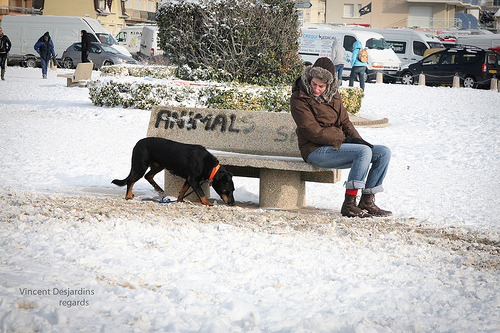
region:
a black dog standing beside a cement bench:
[110, 135, 236, 206]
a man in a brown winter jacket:
[290, 56, 392, 218]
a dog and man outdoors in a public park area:
[110, 56, 392, 216]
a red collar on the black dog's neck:
[209, 161, 219, 181]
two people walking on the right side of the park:
[330, 37, 368, 89]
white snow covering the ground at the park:
[121, 230, 498, 331]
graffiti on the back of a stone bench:
[152, 109, 293, 137]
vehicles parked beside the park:
[0, 13, 499, 85]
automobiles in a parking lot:
[1, 11, 497, 89]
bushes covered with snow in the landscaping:
[87, 63, 287, 106]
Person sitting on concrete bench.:
[81, 37, 413, 247]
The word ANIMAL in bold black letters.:
[138, 97, 264, 135]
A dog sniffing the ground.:
[113, 117, 252, 224]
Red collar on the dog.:
[148, 127, 243, 204]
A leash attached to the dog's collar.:
[148, 133, 236, 216]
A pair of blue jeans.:
[302, 134, 402, 199]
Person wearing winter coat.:
[288, 59, 410, 182]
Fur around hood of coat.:
[279, 46, 350, 121]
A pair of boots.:
[327, 173, 399, 225]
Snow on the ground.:
[11, 82, 485, 317]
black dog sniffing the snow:
[100, 133, 240, 216]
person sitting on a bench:
[287, 48, 404, 225]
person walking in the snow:
[29, 26, 58, 86]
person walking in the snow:
[0, 25, 14, 83]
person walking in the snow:
[75, 25, 96, 69]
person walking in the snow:
[345, 34, 372, 101]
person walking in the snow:
[326, 33, 349, 86]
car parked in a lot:
[397, 44, 499, 93]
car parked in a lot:
[57, 38, 139, 75]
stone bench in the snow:
[142, 94, 348, 217]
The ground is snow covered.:
[84, 215, 305, 326]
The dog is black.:
[113, 119, 243, 221]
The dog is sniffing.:
[107, 112, 257, 221]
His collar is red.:
[195, 146, 223, 187]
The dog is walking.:
[109, 121, 246, 219]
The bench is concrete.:
[147, 87, 346, 229]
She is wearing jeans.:
[309, 124, 405, 204]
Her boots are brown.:
[327, 169, 399, 241]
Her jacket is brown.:
[285, 44, 346, 141]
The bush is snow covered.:
[110, 34, 281, 131]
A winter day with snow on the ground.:
[19, 12, 447, 309]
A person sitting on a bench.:
[243, 43, 427, 254]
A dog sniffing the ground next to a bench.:
[98, 78, 283, 223]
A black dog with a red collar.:
[85, 117, 255, 242]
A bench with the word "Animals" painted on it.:
[113, 80, 288, 225]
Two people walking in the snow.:
[326, 32, 389, 100]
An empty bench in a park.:
[59, 50, 98, 100]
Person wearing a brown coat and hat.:
[276, 40, 407, 252]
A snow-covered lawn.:
[5, 176, 200, 330]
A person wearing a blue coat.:
[344, 35, 378, 97]